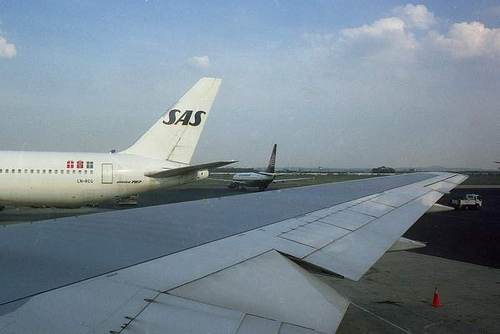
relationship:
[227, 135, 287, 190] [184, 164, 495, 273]
plan on tarmac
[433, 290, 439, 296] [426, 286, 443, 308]
strip on traffic cone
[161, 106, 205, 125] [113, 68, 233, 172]
writing on tail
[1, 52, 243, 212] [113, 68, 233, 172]
plane has tail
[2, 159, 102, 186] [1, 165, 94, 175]
row of windows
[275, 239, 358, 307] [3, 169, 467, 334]
hole in wing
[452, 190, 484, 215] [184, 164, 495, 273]
truck on tarmac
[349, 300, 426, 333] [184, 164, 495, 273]
line on tarmac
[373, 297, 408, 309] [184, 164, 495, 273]
spot on tarmac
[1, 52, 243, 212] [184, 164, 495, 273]
plane on tarmac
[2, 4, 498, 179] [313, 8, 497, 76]
sky has clouds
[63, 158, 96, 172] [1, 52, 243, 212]
flags on plane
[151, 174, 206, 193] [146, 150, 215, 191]
side of engine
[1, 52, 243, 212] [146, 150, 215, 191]
plane has engine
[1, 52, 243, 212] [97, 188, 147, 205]
plane has stablizer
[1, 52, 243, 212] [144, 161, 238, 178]
plane has wing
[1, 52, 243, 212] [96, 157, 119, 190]
plane has door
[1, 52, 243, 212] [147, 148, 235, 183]
plane has wing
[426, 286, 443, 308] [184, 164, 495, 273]
traffic cone on tarmac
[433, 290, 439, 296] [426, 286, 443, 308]
strip on top of traffic cone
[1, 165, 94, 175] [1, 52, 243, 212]
windows on plane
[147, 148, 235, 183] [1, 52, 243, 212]
wing on plane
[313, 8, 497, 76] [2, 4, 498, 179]
clouds in sky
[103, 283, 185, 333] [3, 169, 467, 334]
rivets on wing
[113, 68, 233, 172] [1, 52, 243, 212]
tail of plane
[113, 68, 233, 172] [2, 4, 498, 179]
tail against sky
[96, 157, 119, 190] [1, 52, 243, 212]
door on plane